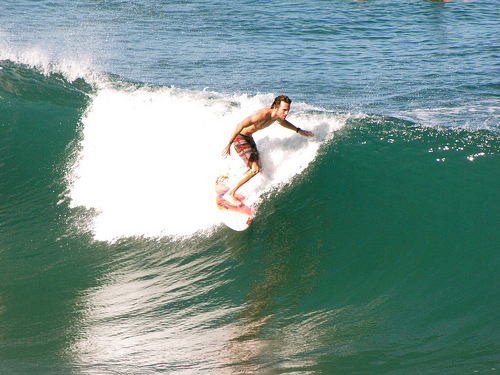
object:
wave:
[1, 40, 491, 158]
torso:
[223, 107, 272, 134]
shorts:
[232, 133, 260, 167]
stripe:
[234, 135, 253, 164]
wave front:
[7, 215, 500, 372]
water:
[1, 1, 500, 375]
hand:
[298, 129, 314, 137]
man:
[222, 95, 315, 207]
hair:
[271, 94, 292, 109]